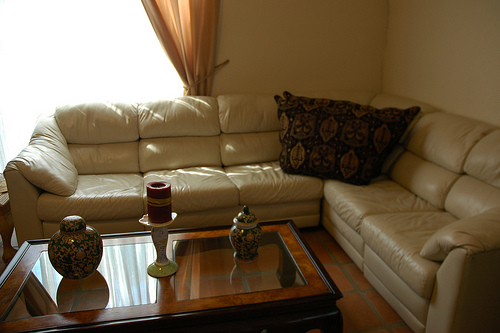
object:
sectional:
[3, 75, 499, 327]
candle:
[140, 182, 177, 278]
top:
[7, 226, 308, 322]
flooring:
[0, 217, 418, 330]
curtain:
[140, 1, 229, 99]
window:
[9, 1, 189, 102]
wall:
[218, 0, 499, 149]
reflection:
[47, 270, 117, 325]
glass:
[3, 227, 305, 320]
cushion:
[268, 83, 425, 181]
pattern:
[304, 133, 362, 159]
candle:
[145, 180, 174, 223]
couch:
[7, 92, 492, 332]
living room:
[3, 11, 498, 326]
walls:
[207, 1, 498, 125]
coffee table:
[1, 217, 345, 329]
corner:
[213, 3, 499, 332]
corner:
[269, 83, 422, 179]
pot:
[230, 202, 259, 261]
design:
[230, 208, 258, 258]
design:
[143, 198, 174, 210]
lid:
[230, 206, 253, 223]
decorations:
[45, 214, 108, 277]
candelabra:
[139, 213, 179, 276]